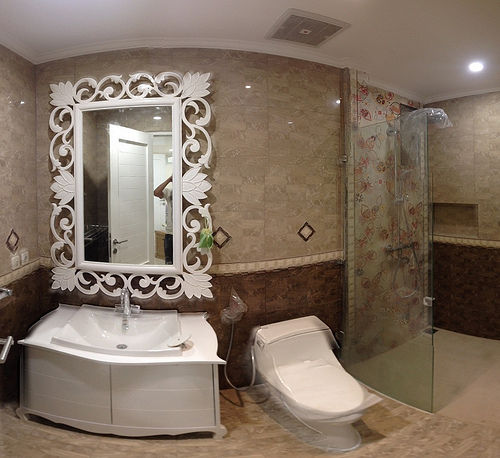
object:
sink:
[16, 302, 228, 367]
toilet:
[252, 314, 384, 456]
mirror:
[48, 71, 215, 302]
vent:
[263, 7, 353, 49]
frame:
[47, 70, 214, 299]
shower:
[348, 68, 500, 431]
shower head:
[420, 107, 449, 125]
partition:
[339, 111, 434, 414]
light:
[467, 61, 484, 74]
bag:
[408, 107, 455, 130]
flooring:
[0, 325, 498, 457]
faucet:
[114, 288, 140, 318]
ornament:
[296, 221, 316, 242]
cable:
[223, 295, 256, 392]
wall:
[0, 44, 500, 408]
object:
[422, 327, 439, 335]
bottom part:
[15, 341, 229, 441]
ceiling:
[1, 3, 500, 105]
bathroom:
[1, 0, 500, 457]